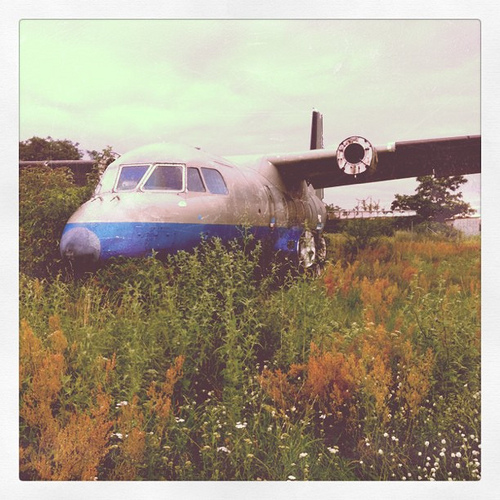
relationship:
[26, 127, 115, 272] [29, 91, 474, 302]
greentrees behind plane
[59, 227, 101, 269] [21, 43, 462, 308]
nose on plane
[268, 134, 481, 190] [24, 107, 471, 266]
wing on plane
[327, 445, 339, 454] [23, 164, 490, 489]
white bud on grass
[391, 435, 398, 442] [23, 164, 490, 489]
white bud on grass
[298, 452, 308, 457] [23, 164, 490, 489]
white bud on grass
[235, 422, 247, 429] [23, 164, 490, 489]
white bud on grass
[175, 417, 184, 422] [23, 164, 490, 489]
white bud on grass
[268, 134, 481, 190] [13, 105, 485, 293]
wing on plane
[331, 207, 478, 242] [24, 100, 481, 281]
building behind plane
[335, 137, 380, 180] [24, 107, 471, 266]
engine on plane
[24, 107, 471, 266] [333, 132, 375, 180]
plane has engine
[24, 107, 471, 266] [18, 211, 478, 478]
plane in grass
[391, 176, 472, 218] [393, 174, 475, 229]
leaves on tree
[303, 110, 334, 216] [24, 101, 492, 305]
tail of a plane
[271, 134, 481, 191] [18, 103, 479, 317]
wing on plane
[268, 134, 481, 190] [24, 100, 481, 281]
wing on plane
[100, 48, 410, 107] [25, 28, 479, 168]
clouds in sky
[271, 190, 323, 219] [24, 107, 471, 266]
windows on plane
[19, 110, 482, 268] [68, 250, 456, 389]
plane in grass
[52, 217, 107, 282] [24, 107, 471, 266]
nose on plane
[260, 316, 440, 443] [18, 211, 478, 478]
plant on grass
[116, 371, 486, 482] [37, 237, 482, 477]
white flowers in grass